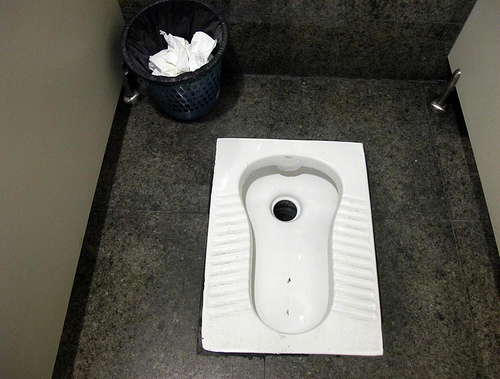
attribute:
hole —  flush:
[262, 191, 338, 235]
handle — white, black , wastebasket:
[115, 83, 152, 109]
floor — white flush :
[190, 129, 397, 358]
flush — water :
[198, 136, 391, 352]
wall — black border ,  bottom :
[56, 81, 141, 363]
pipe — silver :
[434, 64, 461, 116]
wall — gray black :
[254, 8, 463, 77]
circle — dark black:
[270, 190, 302, 230]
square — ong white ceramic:
[192, 125, 397, 358]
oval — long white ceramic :
[243, 151, 354, 333]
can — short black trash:
[112, 10, 242, 121]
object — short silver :
[425, 70, 459, 112]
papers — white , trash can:
[147, 37, 209, 66]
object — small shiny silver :
[117, 82, 146, 112]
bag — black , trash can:
[117, 10, 232, 123]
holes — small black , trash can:
[264, 186, 306, 219]